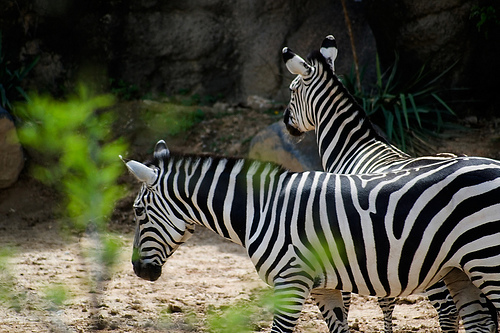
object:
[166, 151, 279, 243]
neck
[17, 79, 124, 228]
tree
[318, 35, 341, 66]
ears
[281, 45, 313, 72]
ear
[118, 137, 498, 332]
zebra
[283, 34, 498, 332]
zebra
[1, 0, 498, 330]
outdoor scene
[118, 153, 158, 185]
ear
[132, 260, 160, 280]
mouth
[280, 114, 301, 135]
mouth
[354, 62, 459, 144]
plant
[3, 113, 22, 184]
rocks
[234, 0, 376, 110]
rocky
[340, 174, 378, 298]
stripe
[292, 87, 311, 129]
stripe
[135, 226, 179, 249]
stripe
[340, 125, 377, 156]
stripe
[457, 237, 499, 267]
stripe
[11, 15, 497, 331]
park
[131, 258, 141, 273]
black nose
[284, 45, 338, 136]
head